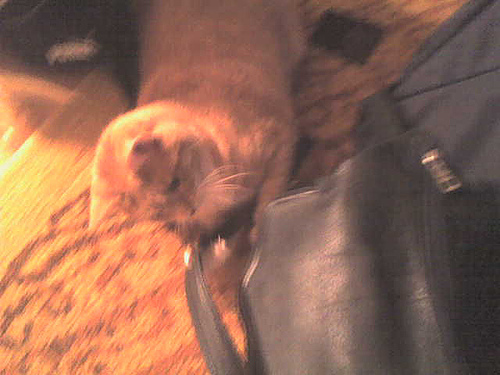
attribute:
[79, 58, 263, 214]
cat — fat, orange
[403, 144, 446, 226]
zipper — gold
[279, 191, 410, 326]
purse — leather, black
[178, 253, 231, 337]
strap — purse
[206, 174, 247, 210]
whiskers — white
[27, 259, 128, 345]
rug — area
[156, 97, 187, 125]
hair —   orange,  cat's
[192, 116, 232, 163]
hair —  cat's,  orange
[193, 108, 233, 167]
hair —  orange,  cat's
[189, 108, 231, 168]
hair —  cat's,  orange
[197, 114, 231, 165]
hair —  orange,  cat's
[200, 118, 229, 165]
hair —  cat's,  orange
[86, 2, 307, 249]
cat — Small,  inside,  brown, orange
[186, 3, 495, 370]
purse —  Black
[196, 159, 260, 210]
whiskers —  cat's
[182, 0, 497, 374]
bag —  leather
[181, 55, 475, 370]
purse — black, leather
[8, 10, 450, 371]
rug — orange